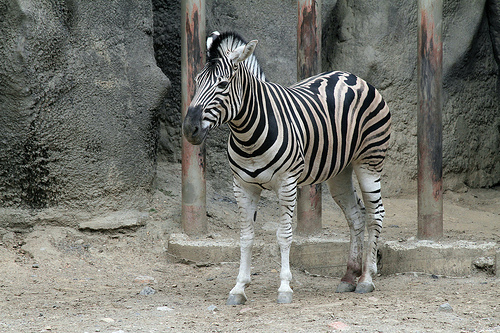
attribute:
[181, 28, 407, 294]
zebra — standing, young, black, white, here, striped, small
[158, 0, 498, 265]
bars — metal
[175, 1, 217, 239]
bar — rusted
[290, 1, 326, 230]
bar — rusted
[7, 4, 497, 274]
wall — gray, stone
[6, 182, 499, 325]
floor — dirt, gravelly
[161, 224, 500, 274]
base — concrete, gray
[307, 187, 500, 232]
patch — dirt, small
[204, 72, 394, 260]
skin — black, white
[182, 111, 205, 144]
nose — black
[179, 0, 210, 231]
pillar — wooden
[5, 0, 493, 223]
rocks — enormous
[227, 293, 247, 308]
foot — black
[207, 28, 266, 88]
hair — black, white, zebra's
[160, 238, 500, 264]
stone — gray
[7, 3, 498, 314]
scene — zoo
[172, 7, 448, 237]
posts — here, metal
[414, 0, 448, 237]
post — black, red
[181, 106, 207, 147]
snout — black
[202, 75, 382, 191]
stripes — black, white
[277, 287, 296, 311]
hoof — back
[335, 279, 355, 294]
hoof — back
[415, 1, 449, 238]
bar — rusted